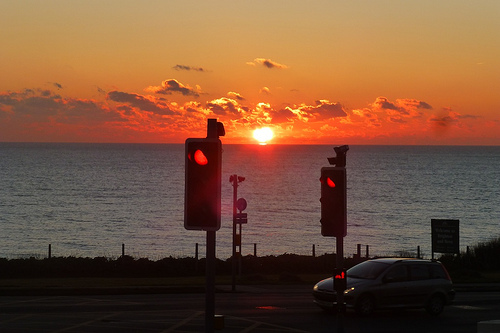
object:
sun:
[252, 126, 275, 144]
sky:
[0, 0, 500, 147]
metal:
[183, 169, 221, 333]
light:
[193, 149, 209, 166]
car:
[313, 255, 457, 317]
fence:
[0, 245, 500, 267]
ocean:
[2, 146, 500, 251]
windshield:
[347, 260, 394, 280]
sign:
[431, 219, 460, 255]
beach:
[0, 257, 499, 286]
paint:
[449, 304, 491, 313]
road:
[0, 291, 496, 332]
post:
[121, 243, 125, 259]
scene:
[0, 1, 499, 333]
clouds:
[2, 55, 500, 143]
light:
[313, 285, 318, 292]